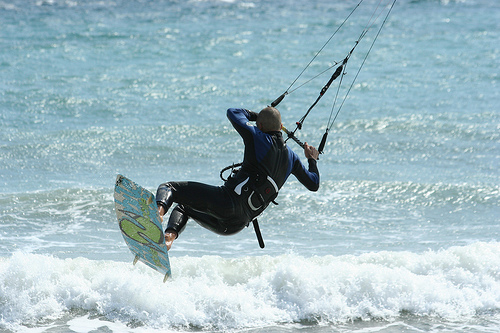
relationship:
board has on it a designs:
[106, 153, 182, 290] [117, 209, 162, 255]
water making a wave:
[361, 110, 478, 222] [288, 245, 488, 322]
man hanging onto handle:
[153, 95, 330, 256] [268, 95, 333, 160]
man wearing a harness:
[153, 95, 330, 256] [226, 153, 286, 227]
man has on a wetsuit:
[153, 95, 330, 256] [155, 111, 326, 232]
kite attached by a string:
[351, 2, 498, 35] [286, 11, 394, 115]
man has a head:
[153, 95, 330, 256] [253, 105, 286, 139]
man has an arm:
[153, 95, 330, 256] [287, 145, 323, 193]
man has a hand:
[153, 95, 330, 256] [300, 139, 325, 163]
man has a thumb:
[153, 95, 330, 256] [300, 138, 312, 154]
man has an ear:
[153, 95, 330, 256] [254, 120, 267, 134]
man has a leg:
[153, 95, 330, 256] [144, 179, 227, 221]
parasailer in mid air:
[153, 95, 330, 256] [77, 111, 349, 314]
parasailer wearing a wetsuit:
[77, 111, 349, 314] [155, 111, 326, 232]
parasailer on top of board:
[153, 95, 330, 256] [106, 153, 182, 290]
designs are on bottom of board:
[115, 190, 167, 273] [106, 153, 182, 290]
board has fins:
[106, 153, 182, 290] [126, 249, 186, 283]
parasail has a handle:
[284, 7, 365, 176] [268, 95, 333, 160]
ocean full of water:
[35, 13, 472, 255] [361, 110, 478, 222]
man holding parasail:
[153, 95, 330, 256] [284, 7, 365, 176]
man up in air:
[153, 95, 330, 256] [77, 111, 349, 314]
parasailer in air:
[153, 95, 330, 256] [77, 111, 349, 314]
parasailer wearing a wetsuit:
[153, 95, 330, 256] [155, 111, 326, 232]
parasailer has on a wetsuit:
[153, 95, 330, 256] [155, 111, 326, 232]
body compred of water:
[35, 13, 472, 255] [361, 110, 478, 222]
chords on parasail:
[287, 3, 394, 140] [284, 7, 365, 176]